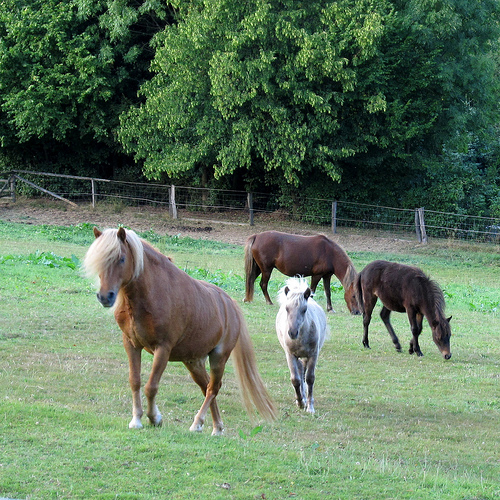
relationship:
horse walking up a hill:
[77, 225, 278, 438] [2, 383, 498, 495]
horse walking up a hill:
[273, 273, 330, 418] [2, 383, 498, 495]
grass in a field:
[4, 220, 496, 497] [3, 194, 495, 499]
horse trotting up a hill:
[248, 262, 350, 403] [0, 182, 500, 498]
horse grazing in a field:
[358, 252, 452, 359] [3, 194, 495, 499]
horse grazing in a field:
[239, 225, 364, 316] [3, 194, 495, 499]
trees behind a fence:
[0, 0, 499, 240] [3, 167, 496, 254]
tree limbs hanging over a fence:
[0, 4, 497, 211] [3, 167, 496, 254]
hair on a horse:
[78, 224, 145, 284] [77, 225, 278, 438]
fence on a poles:
[3, 167, 496, 254] [417, 204, 433, 242]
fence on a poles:
[3, 167, 496, 254] [326, 202, 342, 231]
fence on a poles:
[3, 167, 496, 254] [246, 190, 256, 224]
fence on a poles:
[3, 167, 496, 254] [162, 182, 182, 218]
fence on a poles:
[3, 167, 496, 254] [87, 177, 97, 204]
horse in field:
[352, 259, 450, 361] [18, 242, 90, 493]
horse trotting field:
[273, 273, 330, 418] [10, 228, 39, 308]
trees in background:
[101, 4, 450, 238] [77, 15, 444, 221]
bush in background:
[188, 167, 497, 217] [77, 15, 444, 221]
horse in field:
[241, 229, 364, 316] [12, 246, 93, 486]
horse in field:
[355, 254, 454, 365] [19, 228, 89, 483]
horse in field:
[241, 229, 364, 316] [19, 228, 89, 483]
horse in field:
[273, 273, 330, 418] [19, 228, 89, 483]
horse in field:
[77, 225, 278, 438] [19, 228, 89, 483]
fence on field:
[0, 169, 498, 245] [12, 203, 82, 478]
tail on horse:
[229, 301, 280, 424] [77, 225, 278, 438]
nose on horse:
[94, 288, 117, 308] [77, 225, 278, 438]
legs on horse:
[184, 369, 230, 434] [74, 223, 261, 456]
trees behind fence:
[3, 1, 498, 215] [3, 167, 496, 254]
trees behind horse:
[127, 4, 432, 171] [77, 225, 278, 438]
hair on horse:
[78, 224, 145, 281] [65, 226, 277, 441]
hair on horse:
[78, 224, 145, 281] [269, 274, 329, 416]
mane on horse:
[85, 224, 145, 289] [77, 225, 278, 438]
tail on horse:
[225, 299, 284, 432] [74, 223, 261, 456]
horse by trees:
[239, 225, 364, 316] [49, 9, 490, 175]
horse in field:
[77, 225, 278, 438] [7, 230, 99, 491]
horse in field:
[273, 273, 330, 418] [2, 220, 493, 455]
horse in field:
[241, 229, 364, 316] [3, 194, 495, 499]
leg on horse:
[186, 357, 236, 442] [60, 220, 250, 442]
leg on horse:
[284, 354, 306, 412] [279, 288, 338, 419]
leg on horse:
[361, 296, 376, 350] [358, 260, 469, 381]